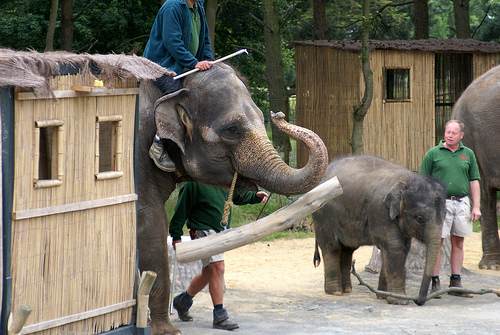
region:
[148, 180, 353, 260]
a piece of wood being carried by an elephant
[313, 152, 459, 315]
a baby elephant picking up a stick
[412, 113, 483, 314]
a man with a green shirt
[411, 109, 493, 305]
a man wearing shorts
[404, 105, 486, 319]
a man wearing boots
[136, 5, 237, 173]
a person on an elephant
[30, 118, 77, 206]
a window to a small building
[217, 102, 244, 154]
the eye of an elephant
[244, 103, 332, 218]
the trunk of an elephant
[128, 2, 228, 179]
a person wearing a blue jacket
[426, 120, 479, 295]
man in green shirt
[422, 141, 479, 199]
green short on man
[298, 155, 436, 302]
baby elephant with stick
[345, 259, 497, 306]
stick that baby elephant is carrying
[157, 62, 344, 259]
large elephant carrying log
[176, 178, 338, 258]
log elephant is carrying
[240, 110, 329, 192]
curled trunk of elephant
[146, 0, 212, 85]
person in blue jacket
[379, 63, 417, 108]
window on building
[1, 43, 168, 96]
thatched roof on building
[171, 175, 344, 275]
a white log on a rope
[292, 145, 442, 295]
a small baby elephant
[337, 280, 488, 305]
a tree limb in a trunk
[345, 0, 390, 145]
a tree in front of a building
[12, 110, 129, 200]
windows on a shack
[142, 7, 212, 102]
a man on a elephant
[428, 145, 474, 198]
a green shirt on a man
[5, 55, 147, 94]
a straw roof on a building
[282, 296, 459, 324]
a dirt cover road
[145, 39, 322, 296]
a elephant carrying a log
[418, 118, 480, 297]
the man standing next to a small elephant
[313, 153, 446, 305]
the small elephant next to the man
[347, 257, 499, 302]
the tree branch in the elephant's trunk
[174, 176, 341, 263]
the log carried by the elephant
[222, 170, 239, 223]
the rope in the elephant's mouth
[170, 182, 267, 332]
the man walking next to the elephant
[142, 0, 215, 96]
the man on the elephant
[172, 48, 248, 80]
the stick in the man's hand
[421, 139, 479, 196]
the green shirt on the man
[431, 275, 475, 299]
the shoes on the man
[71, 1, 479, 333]
elephants in an area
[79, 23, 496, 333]
elephants carrying sticks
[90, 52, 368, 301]
an elephant carrying a log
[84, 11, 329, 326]
a person riding an elephant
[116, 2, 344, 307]
a person riding a large elephant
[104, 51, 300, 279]
a large elephant carrying a log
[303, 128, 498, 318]
a small elephant carrying a stick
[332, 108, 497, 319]
a man standing next to the small elephant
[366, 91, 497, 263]
a man wearing a green shirt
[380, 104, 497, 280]
a man wearing khakis